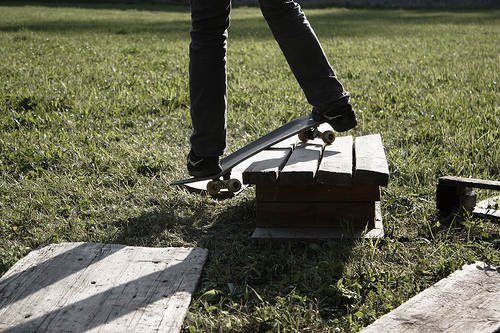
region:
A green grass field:
[4, 111, 91, 201]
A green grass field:
[234, 261, 364, 330]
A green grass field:
[394, 216, 450, 284]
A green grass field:
[395, 107, 447, 173]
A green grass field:
[6, 68, 58, 170]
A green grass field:
[78, 36, 173, 139]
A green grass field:
[341, 21, 484, 71]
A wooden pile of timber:
[251, 154, 378, 247]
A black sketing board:
[174, 114, 341, 185]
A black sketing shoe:
[305, 85, 368, 129]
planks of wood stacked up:
[240, 128, 387, 188]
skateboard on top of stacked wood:
[165, 96, 351, 196]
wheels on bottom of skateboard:
[204, 176, 243, 193]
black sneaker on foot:
[301, 93, 371, 132]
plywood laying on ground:
[0, 238, 216, 331]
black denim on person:
[186, 0, 343, 156]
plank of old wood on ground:
[350, 251, 497, 331]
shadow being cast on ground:
[1, 11, 388, 36]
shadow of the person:
[0, 202, 217, 331]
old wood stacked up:
[431, 168, 497, 223]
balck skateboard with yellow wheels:
[188, 95, 356, 192]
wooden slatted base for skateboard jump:
[248, 128, 390, 236]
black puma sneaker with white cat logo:
[181, 150, 220, 172]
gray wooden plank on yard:
[2, 231, 207, 328]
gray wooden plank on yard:
[356, 254, 498, 330]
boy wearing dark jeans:
[177, 0, 357, 145]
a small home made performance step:
[434, 177, 498, 226]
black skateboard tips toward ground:
[178, 113, 339, 188]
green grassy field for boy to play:
[7, 10, 497, 323]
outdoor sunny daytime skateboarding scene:
[9, 7, 496, 321]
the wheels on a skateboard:
[201, 153, 251, 210]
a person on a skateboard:
[146, 3, 409, 221]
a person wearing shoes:
[163, 77, 388, 192]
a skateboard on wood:
[185, 77, 394, 219]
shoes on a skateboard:
[151, 49, 434, 201]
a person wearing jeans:
[102, 22, 349, 175]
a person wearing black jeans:
[155, 7, 392, 184]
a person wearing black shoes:
[157, 30, 446, 214]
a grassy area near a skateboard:
[117, 0, 411, 218]